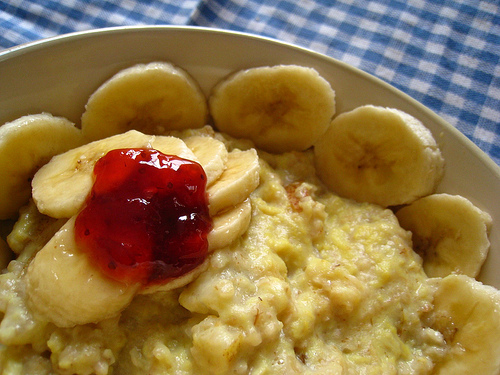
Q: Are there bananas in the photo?
A: Yes, there is a banana.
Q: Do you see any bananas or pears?
A: Yes, there is a banana.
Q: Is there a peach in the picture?
A: No, there are no peaches.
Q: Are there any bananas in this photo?
A: Yes, there is a banana.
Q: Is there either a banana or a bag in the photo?
A: Yes, there is a banana.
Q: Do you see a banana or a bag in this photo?
A: Yes, there is a banana.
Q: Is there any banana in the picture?
A: Yes, there are bananas.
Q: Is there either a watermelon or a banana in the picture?
A: Yes, there are bananas.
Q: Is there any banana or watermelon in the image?
A: Yes, there are bananas.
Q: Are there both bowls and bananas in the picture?
A: Yes, there are both bananas and a bowl.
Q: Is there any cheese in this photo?
A: No, there is no cheese.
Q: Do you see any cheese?
A: No, there is no cheese.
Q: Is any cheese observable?
A: No, there is no cheese.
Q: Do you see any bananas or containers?
A: Yes, there are bananas.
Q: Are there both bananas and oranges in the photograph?
A: No, there are bananas but no oranges.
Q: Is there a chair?
A: No, there are no chairs.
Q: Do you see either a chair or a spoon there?
A: No, there are no chairs or spoons.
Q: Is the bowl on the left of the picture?
A: Yes, the bowl is on the left of the image.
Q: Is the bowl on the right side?
A: No, the bowl is on the left of the image.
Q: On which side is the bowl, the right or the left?
A: The bowl is on the left of the image.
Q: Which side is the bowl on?
A: The bowl is on the left of the image.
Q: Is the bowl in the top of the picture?
A: Yes, the bowl is in the top of the image.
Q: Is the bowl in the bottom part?
A: No, the bowl is in the top of the image.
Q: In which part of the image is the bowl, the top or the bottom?
A: The bowl is in the top of the image.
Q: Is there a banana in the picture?
A: Yes, there are bananas.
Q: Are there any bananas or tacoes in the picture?
A: Yes, there are bananas.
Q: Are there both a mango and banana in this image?
A: No, there are bananas but no mangoes.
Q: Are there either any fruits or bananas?
A: Yes, there are bananas.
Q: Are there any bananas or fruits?
A: Yes, there are bananas.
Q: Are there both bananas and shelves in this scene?
A: No, there are bananas but no shelves.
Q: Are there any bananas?
A: Yes, there is a banana.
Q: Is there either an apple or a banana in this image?
A: Yes, there is a banana.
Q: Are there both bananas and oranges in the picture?
A: No, there is a banana but no oranges.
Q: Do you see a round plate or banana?
A: Yes, there is a round banana.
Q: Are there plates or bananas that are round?
A: Yes, the banana is round.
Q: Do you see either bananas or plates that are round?
A: Yes, the banana is round.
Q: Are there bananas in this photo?
A: Yes, there are bananas.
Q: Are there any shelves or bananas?
A: Yes, there are bananas.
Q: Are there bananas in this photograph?
A: Yes, there is a banana.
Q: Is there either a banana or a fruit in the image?
A: Yes, there is a banana.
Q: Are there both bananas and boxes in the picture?
A: No, there is a banana but no boxes.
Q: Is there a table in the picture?
A: Yes, there is a table.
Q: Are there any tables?
A: Yes, there is a table.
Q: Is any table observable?
A: Yes, there is a table.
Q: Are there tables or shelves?
A: Yes, there is a table.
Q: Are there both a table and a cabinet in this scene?
A: No, there is a table but no cabinets.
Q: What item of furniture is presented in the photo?
A: The piece of furniture is a table.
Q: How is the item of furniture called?
A: The piece of furniture is a table.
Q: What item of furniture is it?
A: The piece of furniture is a table.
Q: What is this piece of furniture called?
A: That is a table.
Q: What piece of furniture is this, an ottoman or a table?
A: That is a table.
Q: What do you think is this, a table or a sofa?
A: This is a table.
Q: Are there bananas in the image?
A: Yes, there is a banana.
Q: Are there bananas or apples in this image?
A: Yes, there is a banana.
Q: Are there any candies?
A: No, there are no candies.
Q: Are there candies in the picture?
A: No, there are no candies.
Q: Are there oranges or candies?
A: No, there are no candies or oranges.